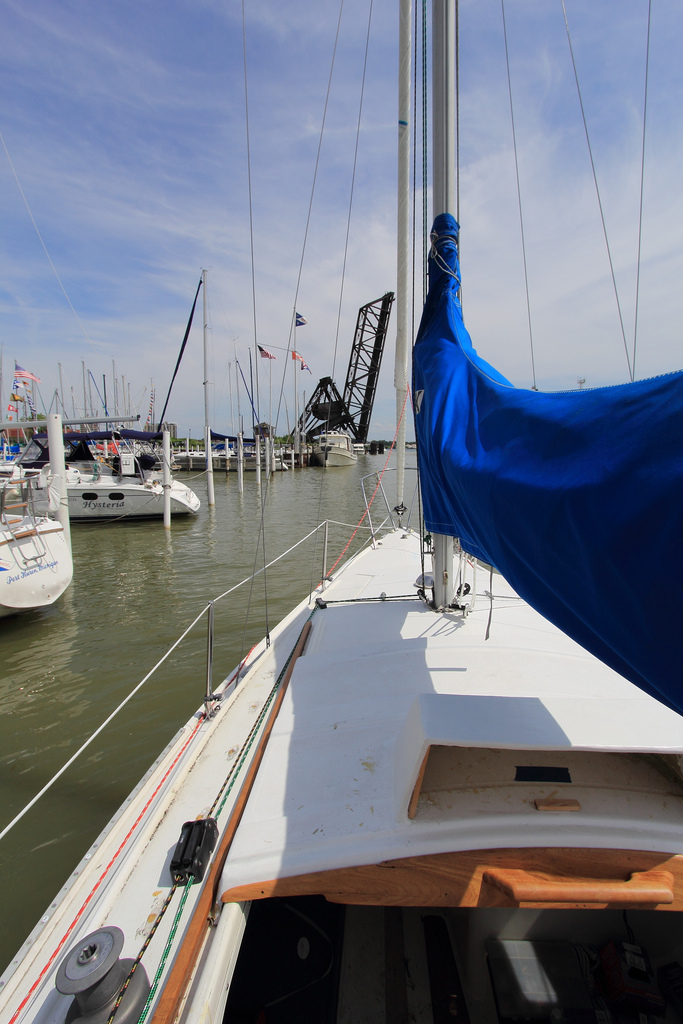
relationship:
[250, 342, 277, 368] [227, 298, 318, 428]
flag on mast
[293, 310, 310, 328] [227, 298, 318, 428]
flag on mast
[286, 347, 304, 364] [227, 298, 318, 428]
flag on mast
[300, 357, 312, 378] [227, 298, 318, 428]
flag on mast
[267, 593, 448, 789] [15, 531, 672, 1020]
shadow on deck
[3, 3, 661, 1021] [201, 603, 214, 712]
boat has pole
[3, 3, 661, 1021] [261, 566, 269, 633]
boat has pole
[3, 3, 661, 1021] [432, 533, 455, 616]
boat has pole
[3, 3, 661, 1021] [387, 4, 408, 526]
boat has pole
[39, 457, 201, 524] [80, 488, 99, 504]
boat has window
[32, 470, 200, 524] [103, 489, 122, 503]
boat has window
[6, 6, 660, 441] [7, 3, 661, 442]
clouds in sky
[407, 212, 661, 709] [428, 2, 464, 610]
canvas hanging from pole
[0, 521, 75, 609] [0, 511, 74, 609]
stern on boat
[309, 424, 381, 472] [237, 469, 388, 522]
boat on water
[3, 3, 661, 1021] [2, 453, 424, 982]
boat on water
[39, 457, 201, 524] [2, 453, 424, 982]
boat on water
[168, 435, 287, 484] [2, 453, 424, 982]
boat on water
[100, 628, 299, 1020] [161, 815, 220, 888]
rope through contraption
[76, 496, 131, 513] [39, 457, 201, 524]
words on boat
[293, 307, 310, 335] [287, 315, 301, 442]
flag on rope